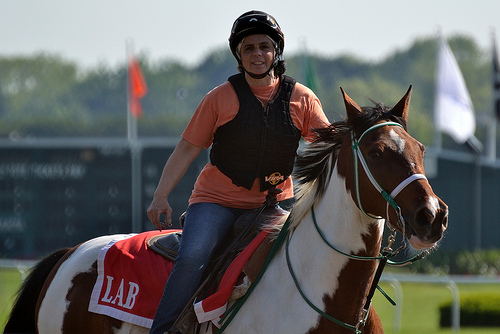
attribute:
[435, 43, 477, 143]
flag — white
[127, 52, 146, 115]
flag — red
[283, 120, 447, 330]
gear — white and green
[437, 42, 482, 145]
flag — white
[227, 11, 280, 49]
helmet — dark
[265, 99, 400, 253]
mane — black and white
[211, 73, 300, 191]
vest — black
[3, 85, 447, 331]
horse — brown, white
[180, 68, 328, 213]
shirt — orange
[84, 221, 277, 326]
blanket — red, white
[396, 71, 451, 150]
ground — white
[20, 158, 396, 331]
horse body — brown and white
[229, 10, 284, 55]
helmet — black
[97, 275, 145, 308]
word — white, capital letters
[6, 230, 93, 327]
black tail — furry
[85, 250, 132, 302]
blanket — red, white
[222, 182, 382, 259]
saddle — black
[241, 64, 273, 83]
chin strap — black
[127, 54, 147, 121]
flag — red